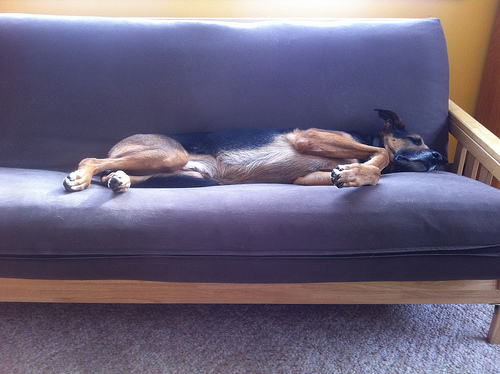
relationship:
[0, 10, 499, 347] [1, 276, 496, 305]
sofa has frame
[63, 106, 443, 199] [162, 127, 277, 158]
dog has spot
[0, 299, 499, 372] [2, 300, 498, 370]
floor has carpet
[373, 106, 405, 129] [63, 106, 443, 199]
ear on dog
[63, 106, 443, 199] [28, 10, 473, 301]
dog on couch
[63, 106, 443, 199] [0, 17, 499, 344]
dog on couch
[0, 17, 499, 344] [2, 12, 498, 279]
couch has cushion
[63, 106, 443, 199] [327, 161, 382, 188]
dog has paw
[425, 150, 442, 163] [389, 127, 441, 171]
black nose on face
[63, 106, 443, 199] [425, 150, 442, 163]
dog has black nose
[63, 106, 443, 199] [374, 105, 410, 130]
dog has ear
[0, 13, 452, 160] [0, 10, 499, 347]
back of sofa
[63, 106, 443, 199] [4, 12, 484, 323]
dog on sofa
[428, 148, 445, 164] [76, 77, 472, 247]
nose on dog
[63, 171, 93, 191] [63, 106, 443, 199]
paw on dog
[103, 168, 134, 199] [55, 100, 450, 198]
paw of dog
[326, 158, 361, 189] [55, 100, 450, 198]
paw of dog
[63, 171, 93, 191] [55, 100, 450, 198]
paw of dog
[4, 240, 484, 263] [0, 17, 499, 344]
line in couch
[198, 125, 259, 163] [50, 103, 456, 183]
fur of dog